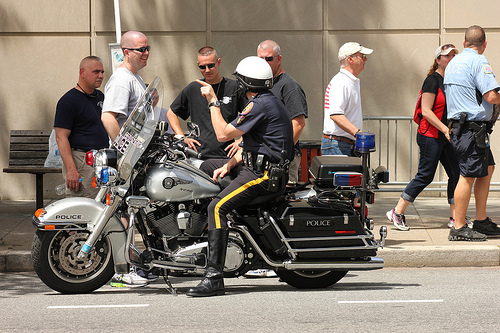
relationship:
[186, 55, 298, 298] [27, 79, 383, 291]
man on motorcycle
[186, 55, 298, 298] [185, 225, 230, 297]
man wearing boots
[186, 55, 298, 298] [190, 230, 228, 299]
man wearing boot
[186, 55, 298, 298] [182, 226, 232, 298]
man wearing black boots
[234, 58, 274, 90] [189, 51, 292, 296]
helmet on policeman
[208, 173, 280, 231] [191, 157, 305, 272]
stripe on pants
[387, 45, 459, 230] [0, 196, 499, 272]
people walking on sidewalk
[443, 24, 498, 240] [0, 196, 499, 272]
man walking on sidewalk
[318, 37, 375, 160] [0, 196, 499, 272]
man walking on sidewalk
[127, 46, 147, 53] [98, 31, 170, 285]
sunglasses on man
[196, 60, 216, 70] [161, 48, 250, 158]
sunglasses on man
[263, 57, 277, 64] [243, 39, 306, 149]
sunglasses on man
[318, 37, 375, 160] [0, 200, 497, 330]
man walking on street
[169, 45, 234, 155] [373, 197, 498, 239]
man standing on sidewalk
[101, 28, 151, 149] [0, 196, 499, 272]
man standing on sidewalk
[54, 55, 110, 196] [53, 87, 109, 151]
man in a shirt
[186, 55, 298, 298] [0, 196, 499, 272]
man on sidewalk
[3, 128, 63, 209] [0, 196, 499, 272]
bench on sidewalk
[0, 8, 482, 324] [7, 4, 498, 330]
photo taken day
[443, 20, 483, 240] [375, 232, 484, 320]
man walking street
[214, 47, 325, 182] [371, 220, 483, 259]
man standing sidewalk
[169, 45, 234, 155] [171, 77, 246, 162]
man in shirt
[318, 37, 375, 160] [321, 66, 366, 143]
man in shirt